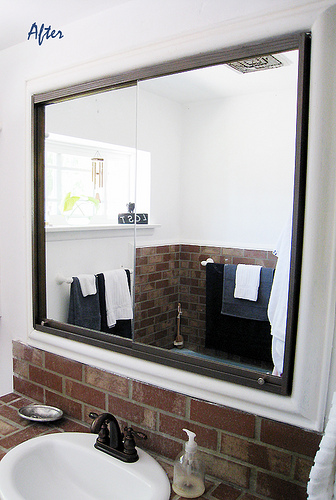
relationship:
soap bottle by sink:
[157, 421, 213, 500] [7, 429, 192, 498]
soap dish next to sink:
[24, 397, 67, 423] [7, 429, 192, 498]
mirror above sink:
[20, 20, 319, 396] [7, 429, 192, 498]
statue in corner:
[122, 200, 147, 225] [114, 183, 153, 235]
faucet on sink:
[91, 410, 143, 458] [7, 429, 192, 498]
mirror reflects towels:
[20, 20, 319, 396] [66, 271, 142, 336]